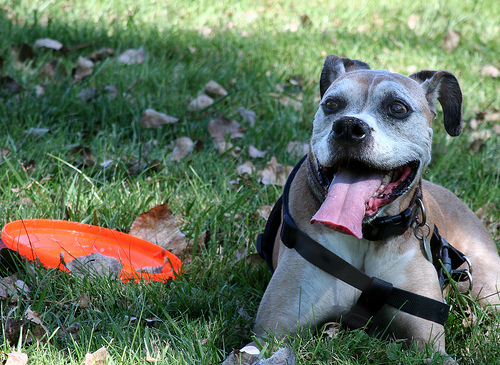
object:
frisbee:
[0, 219, 181, 285]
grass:
[2, 1, 500, 364]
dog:
[218, 55, 499, 364]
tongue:
[309, 165, 385, 241]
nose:
[332, 116, 371, 145]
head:
[304, 55, 464, 241]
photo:
[2, 2, 500, 364]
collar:
[307, 179, 423, 241]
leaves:
[141, 79, 255, 164]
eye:
[385, 99, 416, 120]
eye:
[321, 97, 346, 114]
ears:
[319, 54, 463, 137]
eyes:
[321, 96, 413, 120]